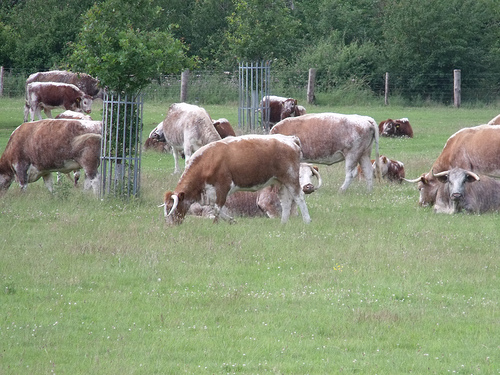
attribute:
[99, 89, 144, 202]
fence — metal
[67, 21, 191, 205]
tree — young, healthy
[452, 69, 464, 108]
pole — wood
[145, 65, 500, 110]
fence — wire, long, metal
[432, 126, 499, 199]
cow — looking at camera, brown, lying down, horned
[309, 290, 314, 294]
flower — white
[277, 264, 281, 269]
flower — white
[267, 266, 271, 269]
flower — white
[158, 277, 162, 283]
flower — white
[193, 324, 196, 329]
flower — white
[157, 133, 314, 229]
cow — grazing, horned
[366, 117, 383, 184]
tail — long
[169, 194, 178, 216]
horn — white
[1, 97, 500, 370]
field — grassy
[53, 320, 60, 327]
flower — small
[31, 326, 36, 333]
flower — small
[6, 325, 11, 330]
flower — small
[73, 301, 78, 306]
flower — small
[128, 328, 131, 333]
flower — small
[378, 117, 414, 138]
cow — darker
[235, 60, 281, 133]
fence — metal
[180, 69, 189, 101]
pole — wooden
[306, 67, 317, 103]
pole — wooden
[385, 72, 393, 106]
pole — wooden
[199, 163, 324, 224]
cow — horned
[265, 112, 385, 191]
cow — grazing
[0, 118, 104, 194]
cow — grazing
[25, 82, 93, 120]
cow — grazing, brown, white, shorter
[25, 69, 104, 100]
cow — grazing, taller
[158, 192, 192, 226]
head — down